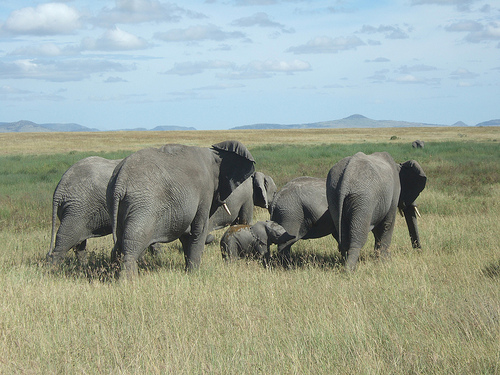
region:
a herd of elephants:
[39, 135, 432, 281]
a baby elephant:
[217, 214, 303, 269]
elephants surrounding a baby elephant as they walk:
[40, 141, 429, 286]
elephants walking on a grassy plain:
[37, 133, 437, 287]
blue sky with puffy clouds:
[2, 2, 495, 127]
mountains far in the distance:
[1, 114, 498, 139]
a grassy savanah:
[1, 130, 497, 373]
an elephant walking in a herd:
[324, 153, 429, 266]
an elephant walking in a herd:
[105, 137, 255, 282]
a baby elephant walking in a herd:
[215, 211, 300, 271]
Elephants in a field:
[50, 141, 424, 269]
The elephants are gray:
[48, 141, 425, 278]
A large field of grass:
[1, 131, 498, 373]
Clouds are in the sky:
[0, 1, 498, 100]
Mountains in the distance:
[1, 113, 498, 133]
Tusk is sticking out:
[222, 204, 230, 216]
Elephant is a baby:
[219, 220, 291, 265]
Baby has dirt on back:
[227, 224, 249, 234]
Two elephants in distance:
[390, 135, 424, 148]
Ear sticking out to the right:
[399, 159, 424, 203]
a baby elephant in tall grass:
[219, 215, 296, 270]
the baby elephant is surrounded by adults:
[24, 128, 433, 290]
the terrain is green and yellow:
[0, 133, 62, 358]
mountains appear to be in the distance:
[4, 108, 496, 143]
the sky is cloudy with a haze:
[3, 6, 498, 122]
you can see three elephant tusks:
[213, 191, 423, 226]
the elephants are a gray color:
[40, 140, 444, 275]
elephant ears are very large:
[207, 136, 260, 217]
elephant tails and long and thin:
[30, 192, 60, 274]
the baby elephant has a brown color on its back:
[217, 219, 249, 241]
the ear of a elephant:
[202, 85, 279, 215]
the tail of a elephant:
[89, 186, 150, 263]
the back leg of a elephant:
[84, 191, 164, 276]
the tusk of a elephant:
[211, 194, 245, 228]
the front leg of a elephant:
[167, 205, 227, 270]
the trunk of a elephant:
[402, 202, 436, 252]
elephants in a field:
[22, 128, 375, 308]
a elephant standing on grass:
[97, 103, 284, 305]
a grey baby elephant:
[191, 211, 302, 284]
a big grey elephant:
[86, 120, 271, 296]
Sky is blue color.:
[142, 83, 313, 113]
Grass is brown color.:
[41, 291, 331, 347]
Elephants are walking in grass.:
[40, 135, 422, 275]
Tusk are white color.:
[220, 196, 231, 216]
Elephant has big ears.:
[195, 120, 265, 207]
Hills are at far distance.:
[12, 110, 488, 136]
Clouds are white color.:
[7, 1, 128, 86]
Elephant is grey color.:
[56, 142, 375, 257]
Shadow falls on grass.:
[24, 225, 196, 310]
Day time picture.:
[32, 40, 454, 373]